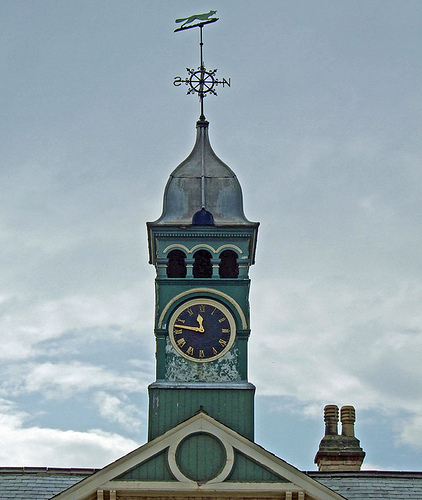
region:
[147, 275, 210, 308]
the clock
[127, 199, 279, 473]
the clock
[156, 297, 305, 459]
the clock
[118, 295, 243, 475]
the clock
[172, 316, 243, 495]
the clock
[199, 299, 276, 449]
the clock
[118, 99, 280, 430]
A clock tower on a building.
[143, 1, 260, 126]
A weather vane on top of the building.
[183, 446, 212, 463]
The boards are light blue.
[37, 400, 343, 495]
The truss has white trim on it.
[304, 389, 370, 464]
Two chimneys on the roof.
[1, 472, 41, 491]
Shingles on the roof.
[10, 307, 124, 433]
Clouds in the sky.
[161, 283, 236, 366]
A clock on the tower.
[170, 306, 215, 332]
The hands on the clock.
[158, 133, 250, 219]
A doom shape on top of the tower.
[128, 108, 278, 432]
the tower on the building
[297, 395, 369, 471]
the chimney on the roof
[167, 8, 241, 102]
the wind vane on the tower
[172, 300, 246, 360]
the clock on the tower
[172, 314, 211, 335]
the hands on the clock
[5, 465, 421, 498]
the roof of the building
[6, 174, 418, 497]
the tower is blue green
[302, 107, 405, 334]
the sky is cloudy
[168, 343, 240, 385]
the paint on the tower is chipped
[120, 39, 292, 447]
the tower is old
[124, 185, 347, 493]
a clock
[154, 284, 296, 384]
a clock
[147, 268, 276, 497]
a clock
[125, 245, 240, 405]
a clock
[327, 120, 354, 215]
the sky is clear and visible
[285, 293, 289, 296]
the sky is clear and visible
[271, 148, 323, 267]
the sky is clear and visible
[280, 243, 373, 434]
the sky is clear and visible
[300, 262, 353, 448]
the sky is clear and visible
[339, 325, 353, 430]
the sky is clear and visible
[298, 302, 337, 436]
the sky is clear and visible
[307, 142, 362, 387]
the sky is clear and visible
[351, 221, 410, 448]
the sky is clear and visible